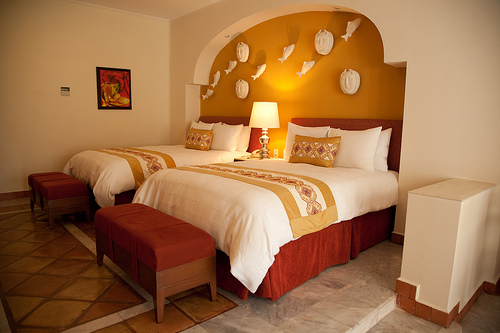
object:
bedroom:
[3, 3, 468, 329]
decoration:
[201, 18, 361, 101]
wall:
[169, 1, 498, 227]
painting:
[96, 66, 132, 110]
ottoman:
[94, 203, 217, 324]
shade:
[249, 102, 280, 129]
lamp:
[249, 101, 280, 159]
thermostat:
[61, 86, 71, 96]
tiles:
[0, 191, 500, 332]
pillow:
[283, 122, 330, 161]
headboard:
[285, 118, 403, 174]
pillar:
[396, 178, 494, 329]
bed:
[63, 116, 263, 208]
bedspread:
[132, 159, 399, 294]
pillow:
[288, 134, 341, 169]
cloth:
[94, 203, 216, 272]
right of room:
[13, 120, 475, 332]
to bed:
[357, 161, 434, 275]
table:
[227, 147, 273, 166]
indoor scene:
[16, 21, 489, 314]